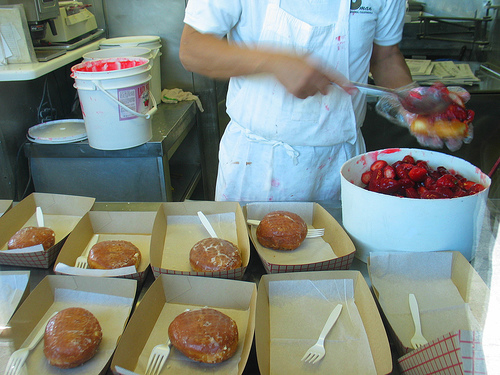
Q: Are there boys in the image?
A: No, there are no boys.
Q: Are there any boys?
A: No, there are no boys.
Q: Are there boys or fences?
A: No, there are no boys or fences.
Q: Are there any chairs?
A: No, there are no chairs.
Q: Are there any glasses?
A: No, there are no glasses.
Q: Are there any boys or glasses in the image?
A: No, there are no glasses or boys.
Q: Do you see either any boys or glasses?
A: No, there are no glasses or boys.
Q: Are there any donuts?
A: Yes, there is a donut.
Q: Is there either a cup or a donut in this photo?
A: Yes, there is a donut.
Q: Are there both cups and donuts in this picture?
A: No, there is a donut but no cups.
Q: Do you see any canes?
A: No, there are no canes.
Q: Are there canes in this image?
A: No, there are no canes.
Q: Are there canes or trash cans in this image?
A: No, there are no canes or trash cans.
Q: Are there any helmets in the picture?
A: No, there are no helmets.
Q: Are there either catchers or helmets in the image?
A: No, there are no helmets or catchers.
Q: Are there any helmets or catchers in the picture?
A: No, there are no helmets or catchers.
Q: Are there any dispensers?
A: No, there are no dispensers.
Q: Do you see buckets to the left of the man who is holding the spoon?
A: Yes, there is a bucket to the left of the man.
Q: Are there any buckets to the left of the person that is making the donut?
A: Yes, there is a bucket to the left of the man.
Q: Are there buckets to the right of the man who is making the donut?
A: No, the bucket is to the left of the man.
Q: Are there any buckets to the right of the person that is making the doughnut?
A: No, the bucket is to the left of the man.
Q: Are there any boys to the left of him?
A: No, there is a bucket to the left of the man.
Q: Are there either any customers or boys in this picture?
A: No, there are no boys or customers.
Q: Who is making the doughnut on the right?
A: The man is making the doughnut.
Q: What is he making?
A: The man is making the donut.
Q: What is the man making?
A: The man is making the donut.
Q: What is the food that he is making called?
A: The food is a donut.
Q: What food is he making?
A: The man is making the donut.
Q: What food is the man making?
A: The man is making the donut.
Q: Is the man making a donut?
A: Yes, the man is making a donut.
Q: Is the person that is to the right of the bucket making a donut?
A: Yes, the man is making a donut.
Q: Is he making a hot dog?
A: No, the man is making a donut.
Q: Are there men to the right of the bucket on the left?
A: Yes, there is a man to the right of the bucket.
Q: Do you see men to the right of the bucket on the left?
A: Yes, there is a man to the right of the bucket.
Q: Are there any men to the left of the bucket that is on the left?
A: No, the man is to the right of the bucket.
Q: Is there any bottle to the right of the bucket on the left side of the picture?
A: No, there is a man to the right of the bucket.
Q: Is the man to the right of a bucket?
A: Yes, the man is to the right of a bucket.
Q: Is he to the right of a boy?
A: No, the man is to the right of a bucket.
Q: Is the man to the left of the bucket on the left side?
A: No, the man is to the right of the bucket.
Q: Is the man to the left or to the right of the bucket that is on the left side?
A: The man is to the right of the bucket.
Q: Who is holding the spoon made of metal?
A: The man is holding the spoon.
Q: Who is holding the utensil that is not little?
A: The man is holding the spoon.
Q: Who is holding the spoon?
A: The man is holding the spoon.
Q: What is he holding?
A: The man is holding the spoon.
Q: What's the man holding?
A: The man is holding the spoon.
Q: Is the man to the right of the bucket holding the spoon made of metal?
A: Yes, the man is holding the spoon.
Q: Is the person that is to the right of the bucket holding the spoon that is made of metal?
A: Yes, the man is holding the spoon.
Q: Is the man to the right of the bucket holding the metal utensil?
A: Yes, the man is holding the spoon.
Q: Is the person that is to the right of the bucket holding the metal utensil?
A: Yes, the man is holding the spoon.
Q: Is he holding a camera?
A: No, the man is holding the spoon.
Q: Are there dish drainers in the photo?
A: No, there are no dish drainers.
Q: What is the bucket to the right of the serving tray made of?
A: The bucket is made of plastic.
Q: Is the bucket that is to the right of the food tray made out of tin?
A: No, the bucket is made of plastic.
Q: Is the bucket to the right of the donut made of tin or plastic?
A: The bucket is made of plastic.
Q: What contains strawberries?
A: The bucket contains strawberries.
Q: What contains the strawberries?
A: The bucket contains strawberries.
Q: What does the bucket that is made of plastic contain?
A: The bucket contains strawberries.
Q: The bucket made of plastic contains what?
A: The bucket contains strawberries.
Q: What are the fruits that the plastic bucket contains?
A: The fruits are strawberries.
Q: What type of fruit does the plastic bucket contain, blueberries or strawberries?
A: The bucket contains strawberries.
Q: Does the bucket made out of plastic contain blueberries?
A: No, the bucket contains strawberries.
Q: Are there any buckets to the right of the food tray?
A: Yes, there is a bucket to the right of the food tray.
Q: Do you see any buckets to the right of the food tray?
A: Yes, there is a bucket to the right of the food tray.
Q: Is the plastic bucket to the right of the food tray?
A: Yes, the bucket is to the right of the food tray.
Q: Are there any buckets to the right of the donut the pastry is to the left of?
A: Yes, there is a bucket to the right of the doughnut.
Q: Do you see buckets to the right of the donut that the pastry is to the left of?
A: Yes, there is a bucket to the right of the doughnut.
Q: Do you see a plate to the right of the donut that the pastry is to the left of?
A: No, there is a bucket to the right of the donut.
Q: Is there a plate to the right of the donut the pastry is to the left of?
A: No, there is a bucket to the right of the donut.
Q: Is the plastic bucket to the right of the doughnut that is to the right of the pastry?
A: Yes, the bucket is to the right of the doughnut.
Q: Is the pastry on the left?
A: Yes, the pastry is on the left of the image.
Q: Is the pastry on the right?
A: No, the pastry is on the left of the image.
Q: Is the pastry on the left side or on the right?
A: The pastry is on the left of the image.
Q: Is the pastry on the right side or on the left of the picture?
A: The pastry is on the left of the image.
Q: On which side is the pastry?
A: The pastry is on the left of the image.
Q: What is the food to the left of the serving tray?
A: The food is a pastry.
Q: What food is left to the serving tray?
A: The food is a pastry.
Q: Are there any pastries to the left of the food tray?
A: Yes, there is a pastry to the left of the food tray.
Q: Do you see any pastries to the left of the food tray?
A: Yes, there is a pastry to the left of the food tray.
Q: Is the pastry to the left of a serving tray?
A: Yes, the pastry is to the left of a serving tray.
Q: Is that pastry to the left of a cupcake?
A: No, the pastry is to the left of a serving tray.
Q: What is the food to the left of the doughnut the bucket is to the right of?
A: The food is a pastry.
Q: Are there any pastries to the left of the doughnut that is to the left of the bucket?
A: Yes, there is a pastry to the left of the donut.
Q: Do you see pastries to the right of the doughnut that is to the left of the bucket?
A: No, the pastry is to the left of the donut.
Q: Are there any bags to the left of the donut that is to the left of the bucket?
A: No, there is a pastry to the left of the donut.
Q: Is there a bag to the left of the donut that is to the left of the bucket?
A: No, there is a pastry to the left of the donut.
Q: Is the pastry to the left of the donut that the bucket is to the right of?
A: Yes, the pastry is to the left of the donut.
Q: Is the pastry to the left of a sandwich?
A: No, the pastry is to the left of the donut.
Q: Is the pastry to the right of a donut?
A: No, the pastry is to the left of a donut.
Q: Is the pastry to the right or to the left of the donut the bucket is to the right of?
A: The pastry is to the left of the doughnut.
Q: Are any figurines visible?
A: No, there are no figurines.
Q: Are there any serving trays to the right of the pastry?
A: Yes, there is a serving tray to the right of the pastry.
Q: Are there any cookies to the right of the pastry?
A: No, there is a serving tray to the right of the pastry.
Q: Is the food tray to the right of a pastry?
A: Yes, the food tray is to the right of a pastry.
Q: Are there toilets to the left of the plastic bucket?
A: No, there is a serving tray to the left of the bucket.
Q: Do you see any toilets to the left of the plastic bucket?
A: No, there is a serving tray to the left of the bucket.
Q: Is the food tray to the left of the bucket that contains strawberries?
A: Yes, the food tray is to the left of the bucket.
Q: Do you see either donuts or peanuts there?
A: Yes, there is a donut.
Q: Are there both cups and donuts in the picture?
A: No, there is a donut but no cups.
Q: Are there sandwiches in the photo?
A: No, there are no sandwiches.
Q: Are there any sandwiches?
A: No, there are no sandwiches.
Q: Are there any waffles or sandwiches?
A: No, there are no sandwiches or waffles.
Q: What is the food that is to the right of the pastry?
A: The food is a donut.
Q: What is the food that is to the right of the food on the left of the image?
A: The food is a donut.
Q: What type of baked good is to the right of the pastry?
A: The food is a donut.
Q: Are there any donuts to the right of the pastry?
A: Yes, there is a donut to the right of the pastry.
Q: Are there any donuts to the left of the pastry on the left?
A: No, the donut is to the right of the pastry.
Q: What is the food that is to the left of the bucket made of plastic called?
A: The food is a donut.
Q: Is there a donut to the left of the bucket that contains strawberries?
A: Yes, there is a donut to the left of the bucket.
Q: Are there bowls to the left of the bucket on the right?
A: No, there is a donut to the left of the bucket.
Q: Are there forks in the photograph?
A: Yes, there is a fork.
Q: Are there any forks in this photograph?
A: Yes, there is a fork.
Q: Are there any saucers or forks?
A: Yes, there is a fork.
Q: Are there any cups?
A: No, there are no cups.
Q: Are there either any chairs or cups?
A: No, there are no cups or chairs.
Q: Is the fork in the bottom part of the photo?
A: Yes, the fork is in the bottom of the image.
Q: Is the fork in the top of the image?
A: No, the fork is in the bottom of the image.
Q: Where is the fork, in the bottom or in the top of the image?
A: The fork is in the bottom of the image.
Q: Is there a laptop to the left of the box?
A: No, there is a fork to the left of the box.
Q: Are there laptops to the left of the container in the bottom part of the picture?
A: No, there is a fork to the left of the box.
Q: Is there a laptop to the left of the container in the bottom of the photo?
A: No, there is a fork to the left of the box.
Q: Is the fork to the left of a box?
A: Yes, the fork is to the left of a box.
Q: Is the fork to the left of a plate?
A: No, the fork is to the left of a box.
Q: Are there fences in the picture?
A: No, there are no fences.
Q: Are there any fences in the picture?
A: No, there are no fences.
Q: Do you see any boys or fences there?
A: No, there are no fences or boys.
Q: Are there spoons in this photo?
A: Yes, there is a spoon.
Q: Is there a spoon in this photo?
A: Yes, there is a spoon.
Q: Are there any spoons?
A: Yes, there is a spoon.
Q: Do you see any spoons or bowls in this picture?
A: Yes, there is a spoon.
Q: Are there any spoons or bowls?
A: Yes, there is a spoon.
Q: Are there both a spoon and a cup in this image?
A: No, there is a spoon but no cups.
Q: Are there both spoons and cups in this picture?
A: No, there is a spoon but no cups.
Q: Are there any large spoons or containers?
A: Yes, there is a large spoon.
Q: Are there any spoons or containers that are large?
A: Yes, the spoon is large.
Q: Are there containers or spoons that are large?
A: Yes, the spoon is large.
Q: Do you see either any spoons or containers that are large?
A: Yes, the spoon is large.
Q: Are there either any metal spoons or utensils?
A: Yes, there is a metal spoon.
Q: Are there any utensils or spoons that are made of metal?
A: Yes, the spoon is made of metal.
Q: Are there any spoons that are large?
A: Yes, there is a large spoon.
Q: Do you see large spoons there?
A: Yes, there is a large spoon.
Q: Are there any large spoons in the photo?
A: Yes, there is a large spoon.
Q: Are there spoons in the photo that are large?
A: Yes, there is a spoon that is large.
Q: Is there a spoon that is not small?
A: Yes, there is a large spoon.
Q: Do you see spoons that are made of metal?
A: Yes, there is a spoon that is made of metal.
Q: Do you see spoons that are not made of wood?
A: Yes, there is a spoon that is made of metal.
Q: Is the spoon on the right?
A: Yes, the spoon is on the right of the image.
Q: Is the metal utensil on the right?
A: Yes, the spoon is on the right of the image.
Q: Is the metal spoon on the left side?
A: No, the spoon is on the right of the image.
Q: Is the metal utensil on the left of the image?
A: No, the spoon is on the right of the image.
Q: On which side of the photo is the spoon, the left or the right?
A: The spoon is on the right of the image.